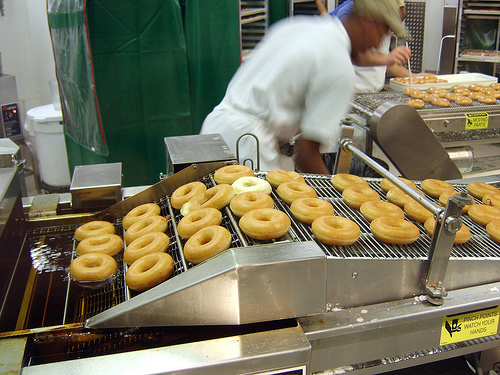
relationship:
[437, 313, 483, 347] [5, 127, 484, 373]
label on machine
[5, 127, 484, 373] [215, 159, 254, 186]
machine with donut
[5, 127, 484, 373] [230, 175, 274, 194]
machine with doughnut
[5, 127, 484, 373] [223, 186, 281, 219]
machine with donut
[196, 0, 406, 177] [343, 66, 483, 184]
man overseeing machine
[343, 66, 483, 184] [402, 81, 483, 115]
machine with donuts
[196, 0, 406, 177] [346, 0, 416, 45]
man with hat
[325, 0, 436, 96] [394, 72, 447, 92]
man checking donuts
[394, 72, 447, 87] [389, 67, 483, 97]
donuts in container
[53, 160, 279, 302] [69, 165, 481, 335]
donuts on conveyor belt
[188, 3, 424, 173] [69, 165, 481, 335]
man behind conveyor belt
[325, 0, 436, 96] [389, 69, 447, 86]
man glazing donuts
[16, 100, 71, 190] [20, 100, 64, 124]
trashcan with lid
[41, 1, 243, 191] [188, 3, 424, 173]
curtain behind man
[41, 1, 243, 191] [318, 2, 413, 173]
curtain behind man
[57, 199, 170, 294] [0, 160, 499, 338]
donuts on belt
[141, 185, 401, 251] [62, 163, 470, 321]
donuts on conveyor belt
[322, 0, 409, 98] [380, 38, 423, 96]
man with spoon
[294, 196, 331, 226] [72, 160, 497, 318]
donut on a conveyor belt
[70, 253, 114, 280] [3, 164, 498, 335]
doughnut on conveyor belt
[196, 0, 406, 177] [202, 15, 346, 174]
man wearing a outfit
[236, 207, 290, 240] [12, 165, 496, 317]
donut on belt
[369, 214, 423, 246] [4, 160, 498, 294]
donut on belt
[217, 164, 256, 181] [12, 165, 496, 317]
donut on belt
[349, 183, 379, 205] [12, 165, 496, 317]
donut on belt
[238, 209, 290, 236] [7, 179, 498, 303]
donut on belt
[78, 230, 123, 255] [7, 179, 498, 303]
donut on belt